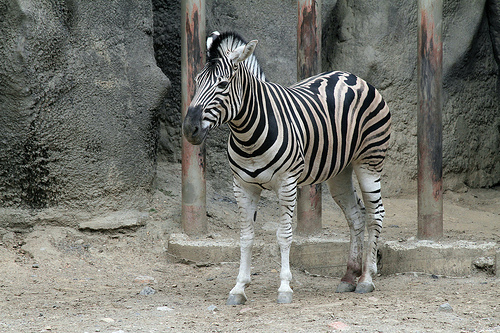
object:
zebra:
[181, 28, 407, 305]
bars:
[166, 0, 498, 265]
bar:
[175, 1, 210, 239]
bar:
[294, 1, 326, 230]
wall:
[0, 4, 497, 274]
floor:
[0, 182, 499, 332]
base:
[165, 228, 500, 278]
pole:
[296, 0, 326, 235]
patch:
[310, 187, 500, 232]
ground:
[243, 72, 500, 189]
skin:
[200, 72, 394, 261]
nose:
[182, 111, 205, 140]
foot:
[275, 289, 294, 306]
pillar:
[179, 0, 207, 231]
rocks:
[0, 0, 493, 223]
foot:
[227, 293, 247, 307]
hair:
[207, 28, 270, 85]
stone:
[162, 238, 500, 264]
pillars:
[177, 0, 447, 240]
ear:
[227, 39, 259, 63]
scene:
[0, 0, 498, 314]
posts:
[180, 0, 446, 237]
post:
[414, 0, 444, 237]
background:
[0, 0, 499, 332]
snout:
[181, 106, 208, 144]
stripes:
[203, 75, 383, 191]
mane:
[206, 29, 273, 85]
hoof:
[277, 287, 296, 304]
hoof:
[227, 292, 246, 305]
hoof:
[356, 280, 377, 294]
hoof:
[335, 279, 355, 292]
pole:
[181, 2, 206, 239]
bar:
[415, 1, 446, 238]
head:
[184, 28, 265, 146]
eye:
[217, 80, 230, 90]